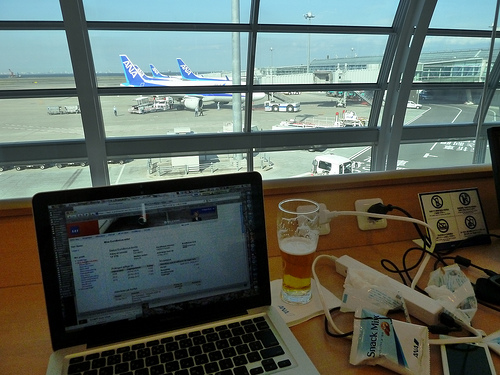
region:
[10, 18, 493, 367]
An aircraft control tower near a tarmac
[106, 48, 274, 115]
Two blue and white planes on the runway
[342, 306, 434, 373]
A blue and white snack pack on the desk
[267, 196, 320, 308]
A pitcher of beer on the desk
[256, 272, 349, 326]
A wihte notepad used as a coaster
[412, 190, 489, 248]
A small sign underneath the window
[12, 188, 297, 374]
An open black and grey laptop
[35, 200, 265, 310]
The screen is powered on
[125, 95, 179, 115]
A small loading vehicle next to the plane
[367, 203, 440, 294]
A black electrical cord on the desk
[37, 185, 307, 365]
MacBook open to Safari web browser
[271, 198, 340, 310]
A glass of beer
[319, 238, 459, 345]
a surge protector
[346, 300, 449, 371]
trash from a bag of snacks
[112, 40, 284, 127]
airplanes docked outside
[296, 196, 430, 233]
power outlets with plugs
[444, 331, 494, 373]
a touch screen cell phone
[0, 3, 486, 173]
a window looking out onto the tarmac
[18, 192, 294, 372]
a laptop computer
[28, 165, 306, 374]
a laptop computer powered on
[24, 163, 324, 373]
Black and white laptop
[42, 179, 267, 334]
Switched on laptop screen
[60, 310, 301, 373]
Black key laptop keyboard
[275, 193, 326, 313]
Glass half full with beer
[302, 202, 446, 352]
White plugged in electrical cord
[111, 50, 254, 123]
Planes parked on tarmac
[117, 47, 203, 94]
ANA plane tail labels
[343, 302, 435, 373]
Bag of snack mix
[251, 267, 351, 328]
White napkin under glass of beer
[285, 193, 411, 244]
White electrical outlets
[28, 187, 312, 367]
The laptop is black and grey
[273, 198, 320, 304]
The glass is clear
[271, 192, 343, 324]
The glass is on a white napkin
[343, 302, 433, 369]
White and blue bag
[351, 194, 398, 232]
The outlet is white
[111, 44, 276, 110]
The plane is blue and white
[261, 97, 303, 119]
White cart with a blue stripe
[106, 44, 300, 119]
The planes are parked on the tarmac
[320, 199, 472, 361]
White and black cords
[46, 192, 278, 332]
The laptop screen is on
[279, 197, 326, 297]
glass half full of beer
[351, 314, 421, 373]
package of airline snack mix treat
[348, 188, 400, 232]
plug in for electrical devices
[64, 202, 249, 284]
computer screen looking at airline schedules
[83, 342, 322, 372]
black keys on silver background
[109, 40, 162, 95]
blue and white logo on tail wing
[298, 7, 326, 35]
tall white lights outside of airport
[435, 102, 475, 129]
white line painted on tarmac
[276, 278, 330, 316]
airport napkin on brown table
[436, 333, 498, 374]
white tablet on table